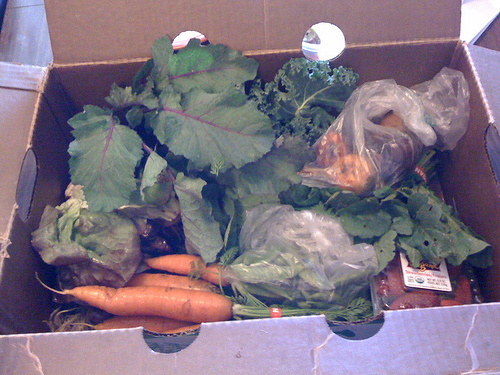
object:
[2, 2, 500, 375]
cardboard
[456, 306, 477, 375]
crack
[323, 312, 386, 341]
cutout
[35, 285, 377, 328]
carrot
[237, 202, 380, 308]
bag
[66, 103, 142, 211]
leaf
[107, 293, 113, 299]
spot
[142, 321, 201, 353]
cutout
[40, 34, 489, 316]
food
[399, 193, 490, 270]
leaf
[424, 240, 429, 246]
hole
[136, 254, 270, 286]
carrots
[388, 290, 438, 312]
strawberries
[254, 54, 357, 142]
lettuce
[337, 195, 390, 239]
kale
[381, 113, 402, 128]
radish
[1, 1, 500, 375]
table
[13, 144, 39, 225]
handle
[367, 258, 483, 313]
container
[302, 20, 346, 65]
hole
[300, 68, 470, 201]
bag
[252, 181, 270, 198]
vegetables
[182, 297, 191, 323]
dirt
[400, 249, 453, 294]
label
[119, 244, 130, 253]
peas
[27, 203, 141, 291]
bag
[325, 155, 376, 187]
peppers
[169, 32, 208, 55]
hole